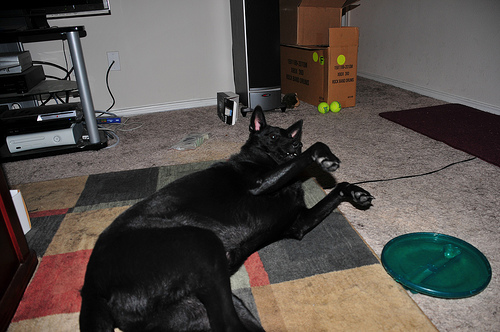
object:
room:
[0, 0, 500, 332]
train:
[30, 151, 99, 268]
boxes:
[278, 0, 359, 109]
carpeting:
[413, 184, 496, 222]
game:
[4, 117, 92, 153]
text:
[332, 64, 355, 84]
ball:
[329, 100, 342, 112]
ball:
[317, 102, 330, 114]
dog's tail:
[76, 291, 117, 332]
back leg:
[141, 226, 245, 332]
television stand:
[67, 30, 110, 152]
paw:
[310, 146, 342, 172]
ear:
[287, 118, 305, 140]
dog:
[77, 104, 376, 331]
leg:
[170, 297, 265, 332]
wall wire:
[98, 52, 126, 125]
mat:
[11, 158, 441, 332]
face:
[255, 125, 304, 157]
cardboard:
[279, 26, 360, 109]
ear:
[248, 105, 268, 133]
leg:
[249, 149, 312, 197]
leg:
[287, 191, 340, 241]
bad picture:
[433, 147, 436, 184]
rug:
[6, 158, 441, 332]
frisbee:
[379, 231, 491, 300]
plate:
[380, 231, 493, 300]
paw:
[349, 186, 377, 211]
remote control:
[80, 157, 225, 206]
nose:
[288, 140, 303, 149]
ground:
[2, 68, 493, 327]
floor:
[2, 76, 500, 332]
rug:
[377, 103, 500, 168]